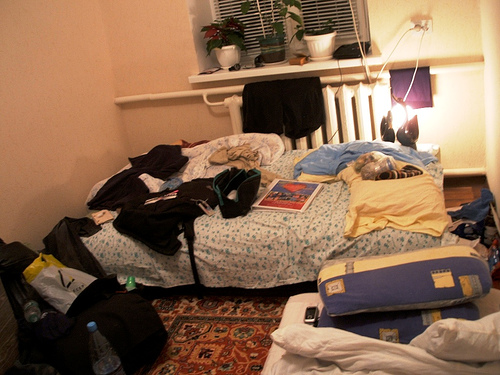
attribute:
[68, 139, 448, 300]
bed — messy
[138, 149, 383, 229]
bed — messy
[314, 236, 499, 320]
pillow — blue, yellow, patchwork pattern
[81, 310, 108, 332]
cap — blue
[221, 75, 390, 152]
radiator — white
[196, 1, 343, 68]
plants — potted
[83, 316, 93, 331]
cap — blue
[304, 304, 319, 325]
phone — black, silver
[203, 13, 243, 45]
plant — small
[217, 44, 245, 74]
pot — white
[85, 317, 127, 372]
bottle — plastic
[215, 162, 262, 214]
bag — black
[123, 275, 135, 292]
bottle — plastic